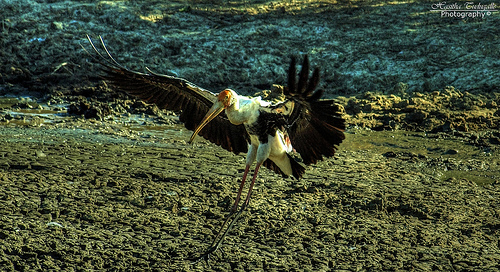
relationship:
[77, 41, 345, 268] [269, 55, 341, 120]
bird with wing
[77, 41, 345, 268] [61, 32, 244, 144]
bird with wing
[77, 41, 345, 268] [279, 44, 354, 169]
bird has tail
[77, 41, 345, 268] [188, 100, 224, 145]
bird has beak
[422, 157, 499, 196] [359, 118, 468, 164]
puddle of water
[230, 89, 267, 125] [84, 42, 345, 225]
patch on bird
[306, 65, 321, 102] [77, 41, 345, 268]
tail feather on bird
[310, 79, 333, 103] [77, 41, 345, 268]
tail feather on bird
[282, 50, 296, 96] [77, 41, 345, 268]
tail feather on bird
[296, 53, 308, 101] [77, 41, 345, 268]
tail feather on bird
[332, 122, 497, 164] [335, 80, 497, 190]
water in rocky depression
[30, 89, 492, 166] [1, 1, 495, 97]
water below slope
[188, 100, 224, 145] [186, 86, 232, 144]
beak at end of head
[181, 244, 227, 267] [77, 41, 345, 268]
grey feet of bird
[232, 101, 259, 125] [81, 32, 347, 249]
neck of bird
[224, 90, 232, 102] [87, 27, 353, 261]
eye of bird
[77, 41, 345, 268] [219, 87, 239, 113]
bird has head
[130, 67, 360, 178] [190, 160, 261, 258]
bird has leg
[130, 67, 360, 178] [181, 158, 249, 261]
bird has leg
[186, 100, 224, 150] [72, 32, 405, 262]
beak on bird